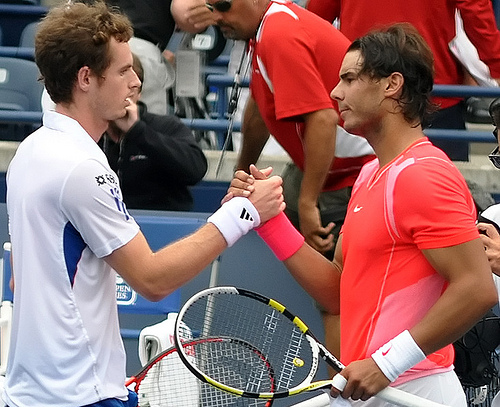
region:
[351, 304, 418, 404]
A wrist band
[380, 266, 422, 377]
A wrist band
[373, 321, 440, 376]
A wrist band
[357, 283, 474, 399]
A wrist band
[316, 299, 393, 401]
A wrist band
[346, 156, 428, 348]
Man wears Red shirt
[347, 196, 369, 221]
White nike sign on shirt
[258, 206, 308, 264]
Pink wrist band on man's arm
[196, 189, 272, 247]
White arm band on man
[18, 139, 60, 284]
Man's wears white shirt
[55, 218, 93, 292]
Blue patch on white shirt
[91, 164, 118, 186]
Black lettering on white shirt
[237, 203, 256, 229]
Black design on white arm band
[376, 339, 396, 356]
Pink nike sign on band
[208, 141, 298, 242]
Two men shake hands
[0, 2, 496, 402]
Two tennis players shaking hands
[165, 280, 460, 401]
White and yellow tennis racket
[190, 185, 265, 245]
Black and white arm band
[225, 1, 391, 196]
Red and white short-sleeve shirt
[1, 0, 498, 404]
Two young athletic men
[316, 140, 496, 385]
Red and pink short-sleeve Nike shirt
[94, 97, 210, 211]
Long-sleeve black jacket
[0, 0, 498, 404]
Sporting event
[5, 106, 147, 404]
White shirt with a blue stripe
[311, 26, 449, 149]
Game face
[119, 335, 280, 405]
a red and black racket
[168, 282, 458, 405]
a yellow black and white racket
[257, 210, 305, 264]
a red wristband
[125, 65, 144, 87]
the nose of a man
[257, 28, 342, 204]
the arm of a man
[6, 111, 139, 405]
a white and blue shirt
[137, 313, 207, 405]
a white towel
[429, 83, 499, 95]
a blue pole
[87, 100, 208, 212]
a black jacket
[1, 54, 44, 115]
a gray suit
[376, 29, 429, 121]
Guy has brown hair.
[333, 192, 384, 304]
Man wearing red shirt.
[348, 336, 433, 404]
White sweat band around man's wrist.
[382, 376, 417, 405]
White grip on racket.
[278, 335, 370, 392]
Man holding tennis racket.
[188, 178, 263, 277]
White wrist band on man's wrist.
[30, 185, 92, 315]
Man wearing white shirt.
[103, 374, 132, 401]
Man is wearing blue shorts.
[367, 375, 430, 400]
Man wearing white shorts.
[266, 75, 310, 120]
Person wearing red shirt.